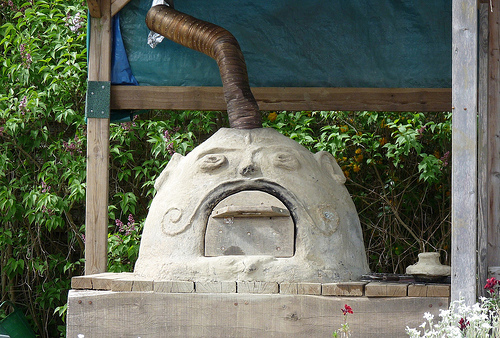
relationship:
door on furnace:
[203, 188, 298, 257] [133, 127, 369, 279]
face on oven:
[156, 139, 345, 262] [129, 101, 371, 281]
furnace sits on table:
[132, 5, 370, 284] [77, 264, 457, 299]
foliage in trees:
[0, 1, 451, 336] [263, 110, 450, 272]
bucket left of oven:
[0, 300, 38, 337] [133, 122, 372, 303]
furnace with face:
[132, 5, 370, 284] [161, 136, 343, 256]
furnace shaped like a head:
[132, 5, 370, 284] [132, 128, 371, 286]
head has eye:
[132, 128, 371, 286] [194, 152, 223, 169]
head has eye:
[132, 128, 371, 286] [271, 149, 301, 169]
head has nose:
[132, 128, 371, 286] [233, 151, 263, 179]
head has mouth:
[156, 121, 349, 265] [186, 157, 322, 267]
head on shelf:
[132, 128, 371, 286] [62, 273, 449, 335]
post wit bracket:
[81, 14, 108, 271] [85, 81, 111, 119]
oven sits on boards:
[155, 160, 345, 248] [67, 261, 425, 310]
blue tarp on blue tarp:
[72, 8, 484, 133] [87, 0, 453, 88]